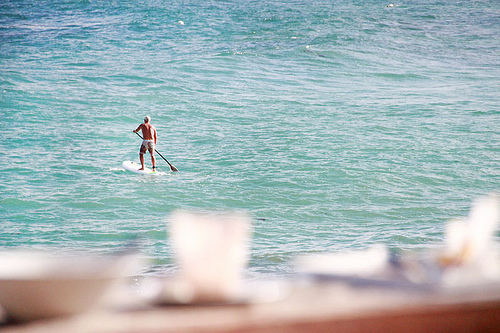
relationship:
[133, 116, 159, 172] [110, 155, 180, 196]
man on surfboard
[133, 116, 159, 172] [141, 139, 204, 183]
man with paddle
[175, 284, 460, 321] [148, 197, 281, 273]
table with cup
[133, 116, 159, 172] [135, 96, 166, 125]
man with hat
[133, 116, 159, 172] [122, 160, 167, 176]
man with paddle board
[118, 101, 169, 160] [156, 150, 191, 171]
man with oar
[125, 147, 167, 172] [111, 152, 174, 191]
legs on surfboard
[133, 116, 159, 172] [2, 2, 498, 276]
man in ocean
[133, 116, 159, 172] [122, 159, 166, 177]
man on paddle board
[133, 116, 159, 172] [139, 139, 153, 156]
man wearing swim trunks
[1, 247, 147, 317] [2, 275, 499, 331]
bowl on ledge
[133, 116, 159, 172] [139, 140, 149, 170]
man has leg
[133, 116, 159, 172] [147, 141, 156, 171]
man has leg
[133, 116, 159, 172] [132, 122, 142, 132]
man has arm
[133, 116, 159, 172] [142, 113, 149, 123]
man has head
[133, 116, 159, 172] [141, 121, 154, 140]
man has back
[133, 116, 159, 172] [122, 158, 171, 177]
man surfing on surfboard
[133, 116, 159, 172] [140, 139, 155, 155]
man wearing shorts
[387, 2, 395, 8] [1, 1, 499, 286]
ball in water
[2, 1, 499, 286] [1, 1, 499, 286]
light reflecting on water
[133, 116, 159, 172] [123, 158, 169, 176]
man standing on paddleboard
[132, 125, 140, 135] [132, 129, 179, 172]
hand holding oar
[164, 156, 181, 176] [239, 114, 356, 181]
paddle in water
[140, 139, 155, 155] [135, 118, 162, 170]
shorts are on mans body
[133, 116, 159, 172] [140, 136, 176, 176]
man holding paddle